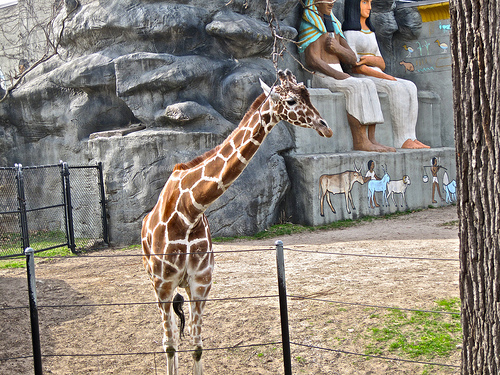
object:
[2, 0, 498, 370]
enclosure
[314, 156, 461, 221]
wall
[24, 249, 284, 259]
wire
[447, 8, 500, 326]
trunk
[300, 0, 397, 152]
statue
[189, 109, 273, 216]
neck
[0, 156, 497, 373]
zoo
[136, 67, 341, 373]
giraffe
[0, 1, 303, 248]
wall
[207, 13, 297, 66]
rock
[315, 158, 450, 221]
picture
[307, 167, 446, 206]
animal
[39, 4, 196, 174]
rocks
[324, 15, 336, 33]
beard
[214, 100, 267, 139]
mane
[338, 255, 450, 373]
grass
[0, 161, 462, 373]
fence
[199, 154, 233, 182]
spot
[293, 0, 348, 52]
head dress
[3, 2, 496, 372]
pen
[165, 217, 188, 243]
spot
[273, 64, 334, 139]
head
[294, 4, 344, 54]
dress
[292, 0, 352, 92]
man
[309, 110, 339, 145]
nose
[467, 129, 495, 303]
gray bark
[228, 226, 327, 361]
pole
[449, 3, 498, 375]
tree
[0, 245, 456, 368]
dirt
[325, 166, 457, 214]
painting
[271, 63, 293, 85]
horns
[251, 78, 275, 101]
ear